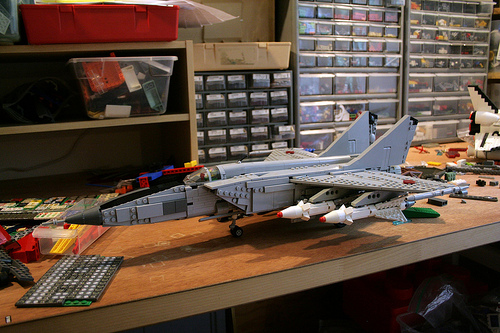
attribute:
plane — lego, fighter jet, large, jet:
[62, 108, 471, 239]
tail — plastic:
[460, 79, 499, 155]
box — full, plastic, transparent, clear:
[68, 51, 179, 120]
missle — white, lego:
[316, 200, 410, 228]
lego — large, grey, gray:
[14, 245, 125, 312]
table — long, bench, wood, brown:
[2, 145, 499, 330]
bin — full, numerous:
[297, 69, 336, 98]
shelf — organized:
[0, 43, 202, 170]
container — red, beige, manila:
[17, 0, 182, 43]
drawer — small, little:
[436, 27, 451, 45]